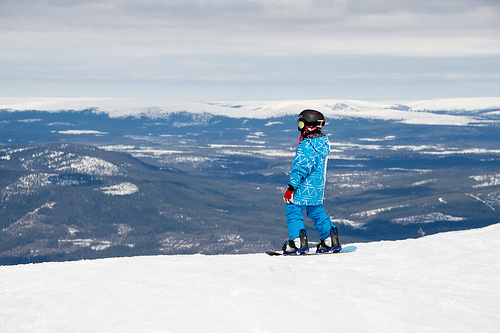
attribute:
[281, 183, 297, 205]
glove — red and white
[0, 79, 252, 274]
valley — large, distant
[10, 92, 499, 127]
mountains — snow-capped, far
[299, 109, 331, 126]
helmet — gray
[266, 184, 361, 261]
pants — bunched up, blue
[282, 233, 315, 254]
boot — blue, black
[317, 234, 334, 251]
boot — black, blue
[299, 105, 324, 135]
helmet — black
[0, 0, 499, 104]
sky — blue, grey, overcast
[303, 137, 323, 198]
jacket — blue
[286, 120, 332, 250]
snowboarder — small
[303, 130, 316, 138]
strap — red